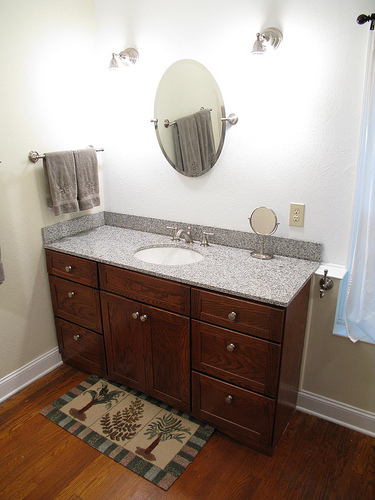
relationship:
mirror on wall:
[247, 204, 279, 259] [3, 2, 372, 412]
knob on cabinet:
[61, 262, 73, 274] [42, 249, 287, 461]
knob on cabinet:
[66, 290, 77, 301] [42, 249, 287, 461]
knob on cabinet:
[72, 332, 82, 343] [42, 249, 287, 461]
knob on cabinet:
[129, 308, 141, 322] [42, 249, 287, 461]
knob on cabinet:
[137, 313, 149, 323] [42, 249, 287, 461]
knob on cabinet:
[225, 309, 241, 323] [42, 249, 287, 461]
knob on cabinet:
[224, 342, 238, 354] [42, 249, 287, 461]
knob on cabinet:
[223, 391, 236, 407] [42, 249, 287, 461]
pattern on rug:
[62, 381, 198, 470] [38, 371, 220, 493]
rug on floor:
[38, 371, 220, 493] [1, 363, 374, 498]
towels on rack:
[41, 147, 102, 212] [29, 145, 107, 162]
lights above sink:
[101, 24, 287, 75] [131, 242, 208, 271]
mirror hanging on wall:
[146, 55, 240, 180] [3, 2, 372, 412]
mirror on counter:
[247, 204, 279, 259] [42, 212, 322, 308]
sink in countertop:
[131, 242, 208, 271] [42, 212, 322, 308]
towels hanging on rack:
[41, 147, 102, 212] [29, 145, 107, 162]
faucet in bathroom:
[173, 228, 194, 248] [3, 2, 372, 498]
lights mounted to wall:
[101, 24, 287, 75] [3, 2, 372, 412]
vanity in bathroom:
[38, 55, 327, 456] [3, 2, 372, 498]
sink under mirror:
[131, 242, 208, 271] [247, 204, 279, 259]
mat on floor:
[38, 371, 220, 493] [1, 363, 374, 498]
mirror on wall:
[146, 55, 240, 180] [3, 2, 372, 412]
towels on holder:
[41, 147, 102, 212] [29, 145, 107, 162]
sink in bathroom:
[131, 242, 208, 271] [3, 2, 372, 498]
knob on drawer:
[223, 391, 236, 407] [188, 369, 278, 451]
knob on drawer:
[224, 342, 238, 354] [189, 319, 284, 401]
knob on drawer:
[225, 309, 241, 323] [196, 288, 287, 343]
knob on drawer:
[72, 332, 82, 343] [53, 315, 106, 377]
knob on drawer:
[66, 290, 77, 301] [49, 276, 104, 334]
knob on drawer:
[61, 262, 73, 274] [40, 246, 100, 290]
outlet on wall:
[289, 202, 307, 230] [3, 2, 372, 412]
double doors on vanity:
[94, 262, 195, 423] [38, 55, 327, 456]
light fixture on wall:
[101, 24, 287, 75] [3, 2, 372, 412]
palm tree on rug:
[68, 378, 128, 422] [38, 371, 220, 493]